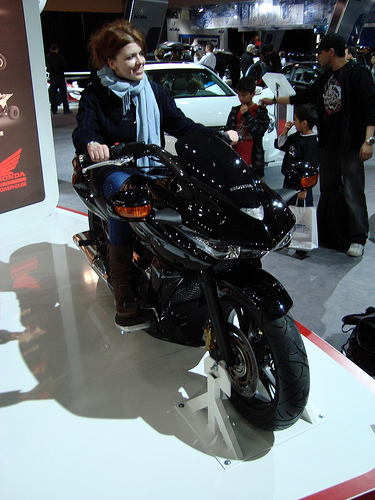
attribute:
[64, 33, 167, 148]
woman — smiling, smilig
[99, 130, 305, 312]
motorcycle — clamped down, black, shiny, displaed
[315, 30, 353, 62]
black cap — baseball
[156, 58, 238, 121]
white car — show car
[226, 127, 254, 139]
bag — white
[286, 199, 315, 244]
bag — white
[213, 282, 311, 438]
front wheel — black